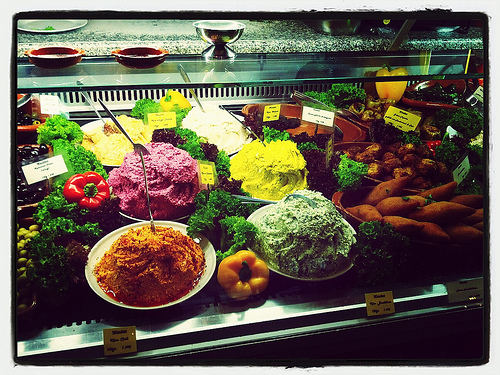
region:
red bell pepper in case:
[62, 167, 112, 208]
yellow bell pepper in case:
[219, 251, 273, 297]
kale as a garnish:
[193, 187, 258, 254]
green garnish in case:
[34, 113, 107, 177]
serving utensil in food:
[135, 149, 159, 239]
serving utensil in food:
[94, 95, 153, 155]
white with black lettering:
[297, 101, 336, 130]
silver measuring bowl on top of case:
[191, 18, 247, 60]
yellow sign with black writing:
[258, 101, 283, 123]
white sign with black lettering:
[19, 152, 70, 191]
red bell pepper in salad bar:
[63, 171, 110, 210]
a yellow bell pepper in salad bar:
[216, 249, 269, 301]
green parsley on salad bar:
[186, 187, 258, 262]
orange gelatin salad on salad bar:
[84, 218, 216, 308]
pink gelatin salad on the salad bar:
[106, 142, 200, 221]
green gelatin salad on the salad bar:
[245, 190, 356, 283]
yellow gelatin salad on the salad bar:
[231, 140, 308, 200]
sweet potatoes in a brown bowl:
[334, 175, 486, 258]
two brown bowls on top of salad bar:
[27, 46, 168, 68]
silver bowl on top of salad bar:
[193, 19, 245, 59]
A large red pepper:
[61, 168, 112, 215]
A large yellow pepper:
[216, 250, 268, 306]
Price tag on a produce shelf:
[358, 286, 400, 323]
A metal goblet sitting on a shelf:
[191, 20, 248, 65]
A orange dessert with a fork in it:
[83, 152, 218, 312]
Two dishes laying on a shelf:
[23, 42, 174, 79]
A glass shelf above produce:
[260, 53, 488, 88]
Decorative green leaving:
[35, 198, 95, 291]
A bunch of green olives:
[14, 219, 49, 321]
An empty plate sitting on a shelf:
[14, 17, 99, 37]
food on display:
[19, 33, 472, 373]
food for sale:
[72, 78, 494, 268]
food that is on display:
[25, 65, 392, 365]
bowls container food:
[48, 68, 469, 318]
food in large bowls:
[43, 89, 490, 346]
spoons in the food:
[44, 46, 497, 343]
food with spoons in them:
[89, 81, 399, 368]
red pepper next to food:
[49, 97, 144, 260]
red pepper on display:
[4, 154, 144, 274]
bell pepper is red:
[45, 148, 122, 220]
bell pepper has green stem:
[52, 168, 122, 217]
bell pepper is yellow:
[200, 242, 277, 317]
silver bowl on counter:
[178, 19, 267, 81]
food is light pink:
[92, 113, 207, 221]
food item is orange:
[91, 213, 207, 310]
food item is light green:
[252, 181, 358, 276]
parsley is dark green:
[182, 184, 254, 246]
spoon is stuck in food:
[89, 95, 164, 175]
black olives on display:
[5, 132, 60, 222]